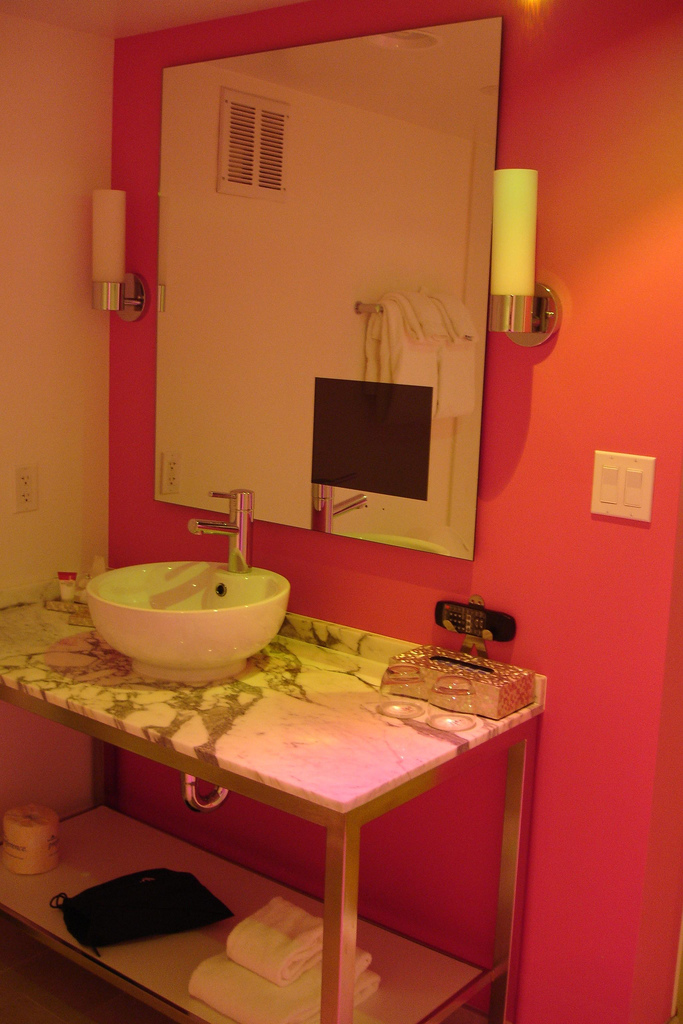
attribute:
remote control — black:
[422, 583, 528, 650]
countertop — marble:
[16, 584, 567, 821]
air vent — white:
[207, 79, 291, 198]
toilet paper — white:
[4, 792, 59, 886]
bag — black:
[54, 856, 235, 956]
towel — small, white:
[203, 890, 342, 1020]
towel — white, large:
[184, 953, 356, 1020]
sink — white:
[73, 547, 306, 683]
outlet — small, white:
[4, 463, 41, 517]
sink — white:
[73, 550, 299, 691]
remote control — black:
[428, 588, 522, 646]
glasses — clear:
[365, 647, 484, 733]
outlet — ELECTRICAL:
[12, 461, 43, 518]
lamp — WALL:
[84, 182, 146, 335]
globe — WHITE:
[90, 183, 134, 279]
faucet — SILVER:
[183, 486, 258, 569]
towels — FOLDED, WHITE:
[182, 889, 375, 1019]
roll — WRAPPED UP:
[8, 797, 60, 873]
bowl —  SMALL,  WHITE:
[80, 555, 296, 684]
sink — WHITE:
[80, 560, 288, 677]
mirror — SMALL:
[299, 367, 434, 502]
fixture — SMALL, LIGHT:
[86, 183, 143, 334]